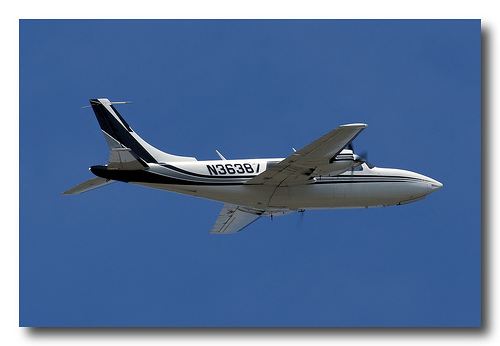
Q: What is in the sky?
A: A PLANE.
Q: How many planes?
A: One.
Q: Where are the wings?
A: On the sides.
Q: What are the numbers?
A: 36387.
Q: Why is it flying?
A: Going to the airport.